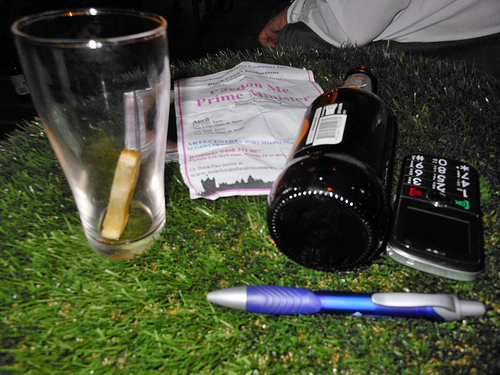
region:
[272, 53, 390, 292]
a bottle of bear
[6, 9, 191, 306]
This is a clear glass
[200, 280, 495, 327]
Blue pen on the grass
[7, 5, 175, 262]
Glass on the grass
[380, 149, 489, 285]
Cell phone on the grass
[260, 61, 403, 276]
Bottle laying on the side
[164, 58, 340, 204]
White paper with prints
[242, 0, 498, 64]
Person sitting on the grass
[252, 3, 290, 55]
Hand of a person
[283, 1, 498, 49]
White colored long sleeved shirt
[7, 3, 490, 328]
Collection of objects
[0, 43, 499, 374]
Very short green grass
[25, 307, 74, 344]
Small patch of green grass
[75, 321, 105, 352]
Small patch of green grass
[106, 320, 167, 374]
Small patch of green grass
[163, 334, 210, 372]
Small patch of green grass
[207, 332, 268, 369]
Small patch of green grass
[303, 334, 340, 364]
Small patch of green grass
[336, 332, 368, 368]
Small patch of green grass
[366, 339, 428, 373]
Small patch of green grass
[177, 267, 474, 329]
Small blue pen on the grass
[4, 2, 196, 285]
Small clear glass in the grass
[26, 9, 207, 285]
an empty tall glass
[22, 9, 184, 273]
a clear tall glass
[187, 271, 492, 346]
a blue pen laying down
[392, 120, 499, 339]
a cell phone on a table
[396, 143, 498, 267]
a black cell phone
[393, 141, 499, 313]
a black cell phone on a table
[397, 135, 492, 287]
a table with a cell phone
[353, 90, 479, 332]
a table with a phone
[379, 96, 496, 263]
a table with a black phone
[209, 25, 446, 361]
a bear bottle laying down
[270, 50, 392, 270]
bottle on the grass.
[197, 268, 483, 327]
blue pen on the grass.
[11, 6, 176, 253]
Cup on the grass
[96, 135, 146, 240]
Orange slice in the glass.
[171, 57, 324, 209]
Paper on the grass.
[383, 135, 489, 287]
Phone on the grass.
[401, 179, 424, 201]
Red button on the phone.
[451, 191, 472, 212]
Green button on the phone.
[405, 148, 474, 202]
white numbers on the phone.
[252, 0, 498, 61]
Person on the grass.